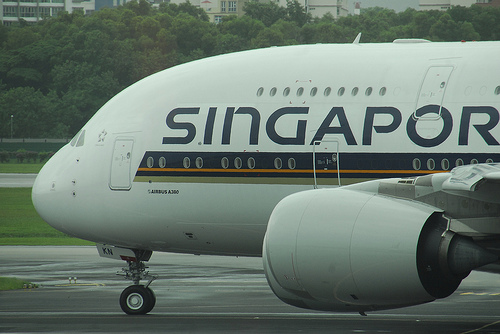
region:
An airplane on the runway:
[12, 8, 497, 326]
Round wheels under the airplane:
[111, 282, 161, 317]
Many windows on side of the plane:
[137, 149, 305, 179]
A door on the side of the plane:
[304, 128, 348, 192]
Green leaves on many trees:
[17, 19, 128, 104]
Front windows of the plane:
[57, 122, 97, 160]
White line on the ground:
[40, 292, 257, 328]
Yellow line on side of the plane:
[133, 158, 408, 190]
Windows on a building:
[0, 0, 75, 26]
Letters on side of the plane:
[153, 94, 498, 159]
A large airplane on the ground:
[26, 32, 498, 315]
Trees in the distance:
[7, 14, 212, 170]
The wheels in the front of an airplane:
[85, 236, 166, 326]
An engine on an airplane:
[265, 171, 488, 312]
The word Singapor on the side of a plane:
[147, 98, 497, 152]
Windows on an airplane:
[248, 78, 390, 108]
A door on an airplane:
[396, 53, 451, 123]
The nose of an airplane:
[23, 60, 188, 279]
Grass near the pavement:
[1, 179, 101, 277]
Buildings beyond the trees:
[4, 0, 368, 30]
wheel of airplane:
[118, 284, 156, 312]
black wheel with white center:
[120, 281, 154, 314]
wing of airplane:
[263, 163, 496, 313]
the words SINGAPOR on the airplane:
[161, 103, 498, 146]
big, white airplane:
[30, 40, 497, 312]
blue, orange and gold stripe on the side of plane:
[133, 150, 498, 181]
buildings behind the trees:
[0, 0, 352, 25]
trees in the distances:
[0, 0, 499, 137]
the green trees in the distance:
[1, 0, 498, 137]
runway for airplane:
[0, 244, 497, 331]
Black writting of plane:
[170, 104, 497, 146]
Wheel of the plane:
[104, 278, 159, 313]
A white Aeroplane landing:
[36, 63, 470, 325]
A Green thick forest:
[26, 15, 116, 130]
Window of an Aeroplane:
[141, 156, 264, 171]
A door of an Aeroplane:
[414, 58, 448, 140]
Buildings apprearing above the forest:
[5, 0, 111, 33]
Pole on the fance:
[6, 111, 20, 166]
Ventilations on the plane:
[255, 85, 394, 100]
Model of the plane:
[101, 243, 116, 257]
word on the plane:
[141, 94, 498, 181]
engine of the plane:
[251, 193, 483, 294]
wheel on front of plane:
[103, 264, 165, 332]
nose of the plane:
[1, 114, 137, 244]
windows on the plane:
[147, 133, 282, 204]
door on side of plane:
[405, 56, 474, 128]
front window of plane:
[51, 116, 102, 167]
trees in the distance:
[32, 28, 115, 87]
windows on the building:
[199, 1, 254, 25]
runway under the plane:
[43, 296, 85, 331]